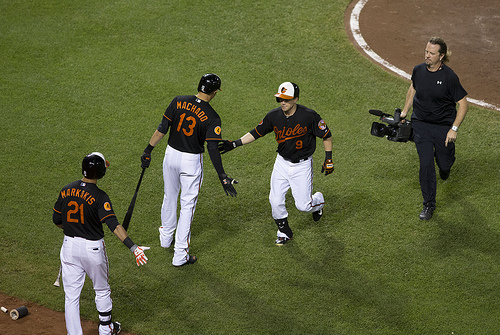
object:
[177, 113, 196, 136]
number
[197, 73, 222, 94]
helmet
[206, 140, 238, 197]
gloves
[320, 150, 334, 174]
gloves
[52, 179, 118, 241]
uniform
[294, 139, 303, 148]
number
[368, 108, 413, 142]
camera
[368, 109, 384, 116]
microphone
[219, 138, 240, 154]
gloves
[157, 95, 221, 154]
jersey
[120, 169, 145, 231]
baseball bat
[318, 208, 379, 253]
ground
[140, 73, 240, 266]
man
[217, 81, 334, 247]
player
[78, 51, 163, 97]
turf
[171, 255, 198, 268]
shoe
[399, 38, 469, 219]
camera man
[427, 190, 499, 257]
shadow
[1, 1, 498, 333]
field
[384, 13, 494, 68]
mound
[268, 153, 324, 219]
wall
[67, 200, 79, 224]
number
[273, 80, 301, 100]
baseball cap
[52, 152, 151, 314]
player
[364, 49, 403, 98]
dirt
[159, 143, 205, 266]
pants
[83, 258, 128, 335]
white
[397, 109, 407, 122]
hand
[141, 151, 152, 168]
hand